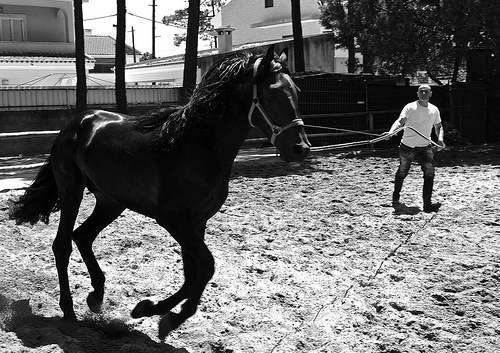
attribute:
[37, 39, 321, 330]
horse — running, black, here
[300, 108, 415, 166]
rope — large, held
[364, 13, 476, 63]
tree — here, tall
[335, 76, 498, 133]
fence — here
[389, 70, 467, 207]
man — bald, standing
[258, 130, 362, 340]
gournd — bare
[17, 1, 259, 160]
building — here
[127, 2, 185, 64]
sky — white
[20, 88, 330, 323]
field — dirty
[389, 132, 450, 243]
pants — dark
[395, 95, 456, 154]
shirt — white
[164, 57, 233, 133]
mane — long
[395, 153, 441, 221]
pants — black